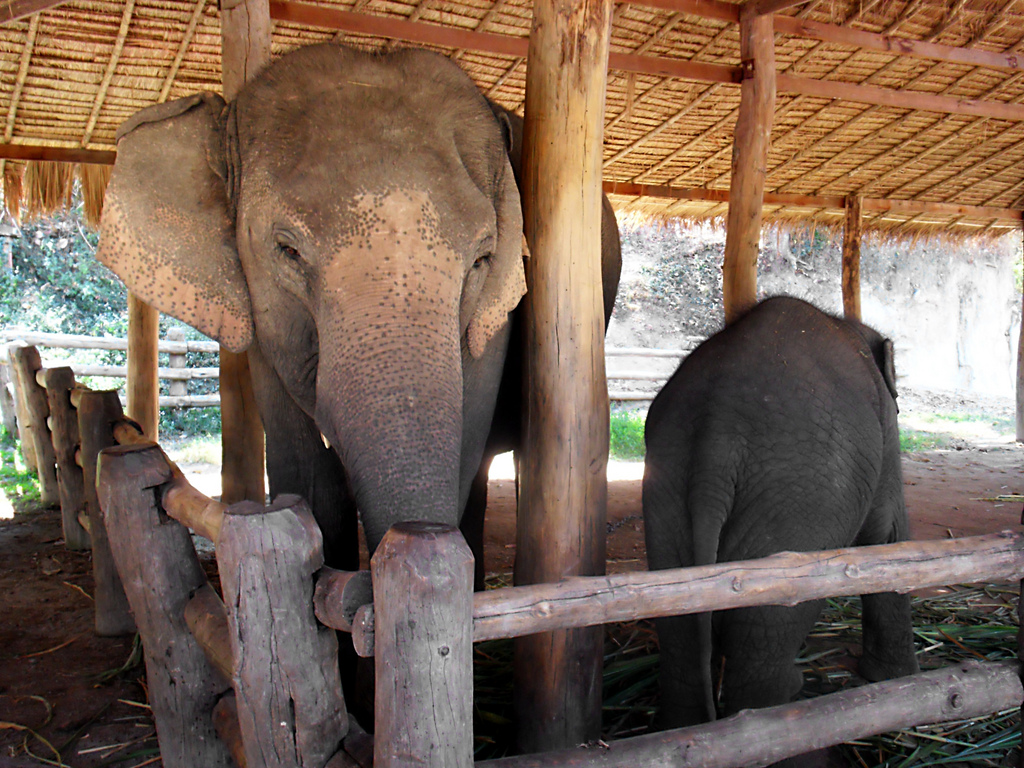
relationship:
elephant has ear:
[95, 39, 623, 729] [96, 91, 254, 354]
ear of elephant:
[73, 83, 236, 401] [95, 39, 623, 729]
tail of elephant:
[669, 421, 773, 746] [640, 293, 919, 724]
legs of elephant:
[628, 498, 823, 766] [632, 289, 939, 758]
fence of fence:
[0, 331, 1022, 767] [2, 327, 1020, 757]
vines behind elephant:
[0, 178, 221, 436] [95, 39, 623, 729]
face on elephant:
[245, 89, 563, 496] [98, 48, 649, 533]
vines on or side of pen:
[0, 178, 221, 436] [8, 325, 992, 758]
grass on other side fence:
[611, 410, 640, 458] [2, 327, 1020, 757]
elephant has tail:
[598, 240, 933, 761] [680, 409, 758, 716]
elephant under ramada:
[640, 293, 919, 724] [0, 1, 1022, 246]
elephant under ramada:
[95, 39, 623, 729] [0, 1, 1022, 246]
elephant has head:
[90, 31, 629, 750] [94, 42, 546, 421]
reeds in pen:
[471, 578, 1019, 767] [17, 265, 1020, 760]